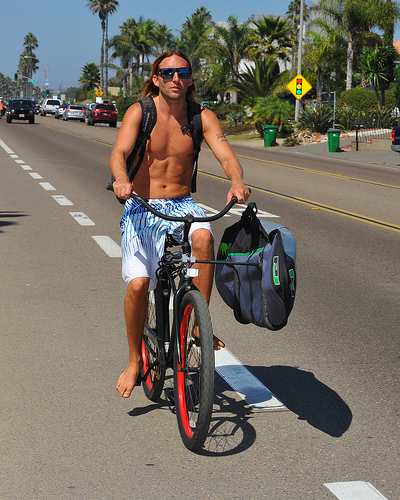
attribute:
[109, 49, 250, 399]
guy — shirtless